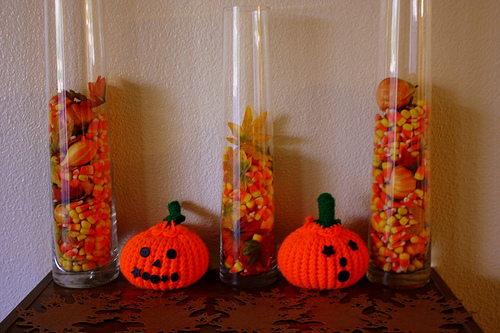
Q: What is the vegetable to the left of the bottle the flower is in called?
A: The vegetable is a pumpkin.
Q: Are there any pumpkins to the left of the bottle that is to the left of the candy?
A: Yes, there is a pumpkin to the left of the bottle.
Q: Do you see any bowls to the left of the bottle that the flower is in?
A: No, there is a pumpkin to the left of the bottle.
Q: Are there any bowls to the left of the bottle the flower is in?
A: No, there is a pumpkin to the left of the bottle.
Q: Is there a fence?
A: No, there are no fences.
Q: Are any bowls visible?
A: No, there are no bowls.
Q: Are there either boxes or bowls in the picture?
A: No, there are no bowls or boxes.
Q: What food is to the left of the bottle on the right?
A: The food is a candy.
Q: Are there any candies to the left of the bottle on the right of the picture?
A: Yes, there is a candy to the left of the bottle.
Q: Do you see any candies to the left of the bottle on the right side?
A: Yes, there is a candy to the left of the bottle.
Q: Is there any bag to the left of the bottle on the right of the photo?
A: No, there is a candy to the left of the bottle.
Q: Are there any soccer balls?
A: No, there are no soccer balls.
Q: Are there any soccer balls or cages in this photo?
A: No, there are no soccer balls or cages.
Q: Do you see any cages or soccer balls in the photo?
A: No, there are no soccer balls or cages.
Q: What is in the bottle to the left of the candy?
A: The flower is in the bottle.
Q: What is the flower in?
A: The flower is in the bottle.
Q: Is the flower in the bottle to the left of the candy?
A: Yes, the flower is in the bottle.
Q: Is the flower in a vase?
A: No, the flower is in the bottle.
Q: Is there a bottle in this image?
A: Yes, there is a bottle.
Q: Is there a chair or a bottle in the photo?
A: Yes, there is a bottle.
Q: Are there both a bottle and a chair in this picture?
A: No, there is a bottle but no chairs.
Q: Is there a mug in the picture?
A: No, there are no mugs.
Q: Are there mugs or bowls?
A: No, there are no mugs or bowls.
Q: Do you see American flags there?
A: No, there are no American flags.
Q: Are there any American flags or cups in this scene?
A: No, there are no American flags or cups.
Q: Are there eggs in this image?
A: No, there are no eggs.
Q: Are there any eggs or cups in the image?
A: No, there are no eggs or cups.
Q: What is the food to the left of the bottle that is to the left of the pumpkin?
A: The food is a candy.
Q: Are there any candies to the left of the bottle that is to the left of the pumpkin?
A: Yes, there is a candy to the left of the bottle.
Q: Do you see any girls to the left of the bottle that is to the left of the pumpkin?
A: No, there is a candy to the left of the bottle.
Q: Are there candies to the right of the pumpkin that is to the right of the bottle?
A: Yes, there is a candy to the right of the pumpkin.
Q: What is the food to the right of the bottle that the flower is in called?
A: The food is a candy.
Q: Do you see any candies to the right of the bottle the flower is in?
A: Yes, there is a candy to the right of the bottle.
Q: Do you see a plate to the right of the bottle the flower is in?
A: No, there is a candy to the right of the bottle.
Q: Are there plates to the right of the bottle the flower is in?
A: No, there is a candy to the right of the bottle.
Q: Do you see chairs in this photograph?
A: No, there are no chairs.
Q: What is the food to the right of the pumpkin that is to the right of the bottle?
A: The food is a candy.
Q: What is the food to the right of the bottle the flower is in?
A: The food is a candy.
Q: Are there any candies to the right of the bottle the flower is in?
A: Yes, there is a candy to the right of the bottle.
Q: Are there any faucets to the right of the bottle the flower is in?
A: No, there is a candy to the right of the bottle.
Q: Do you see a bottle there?
A: Yes, there is a bottle.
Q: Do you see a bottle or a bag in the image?
A: Yes, there is a bottle.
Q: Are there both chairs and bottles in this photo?
A: No, there is a bottle but no chairs.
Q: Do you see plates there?
A: No, there are no plates.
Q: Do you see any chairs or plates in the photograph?
A: No, there are no plates or chairs.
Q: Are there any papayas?
A: No, there are no papayas.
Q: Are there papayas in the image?
A: No, there are no papayas.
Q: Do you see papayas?
A: No, there are no papayas.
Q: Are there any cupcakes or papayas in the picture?
A: No, there are no papayas or cupcakes.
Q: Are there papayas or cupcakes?
A: No, there are no papayas or cupcakes.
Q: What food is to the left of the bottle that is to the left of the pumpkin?
A: The food is a candy.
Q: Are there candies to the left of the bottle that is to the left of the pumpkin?
A: Yes, there is a candy to the left of the bottle.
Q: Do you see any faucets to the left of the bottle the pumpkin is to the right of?
A: No, there is a candy to the left of the bottle.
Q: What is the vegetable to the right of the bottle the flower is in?
A: The vegetable is a pumpkin.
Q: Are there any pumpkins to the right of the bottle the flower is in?
A: Yes, there is a pumpkin to the right of the bottle.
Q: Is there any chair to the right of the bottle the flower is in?
A: No, there is a pumpkin to the right of the bottle.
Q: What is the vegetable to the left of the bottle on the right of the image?
A: The vegetable is a pumpkin.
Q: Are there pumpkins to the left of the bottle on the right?
A: Yes, there is a pumpkin to the left of the bottle.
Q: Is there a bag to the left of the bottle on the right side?
A: No, there is a pumpkin to the left of the bottle.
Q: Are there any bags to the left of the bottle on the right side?
A: No, there is a pumpkin to the left of the bottle.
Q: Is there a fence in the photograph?
A: No, there are no fences.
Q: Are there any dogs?
A: No, there are no dogs.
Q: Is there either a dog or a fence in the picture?
A: No, there are no dogs or fences.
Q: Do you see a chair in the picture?
A: No, there are no chairs.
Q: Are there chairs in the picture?
A: No, there are no chairs.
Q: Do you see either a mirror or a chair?
A: No, there are no chairs or mirrors.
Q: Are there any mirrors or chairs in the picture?
A: No, there are no chairs or mirrors.